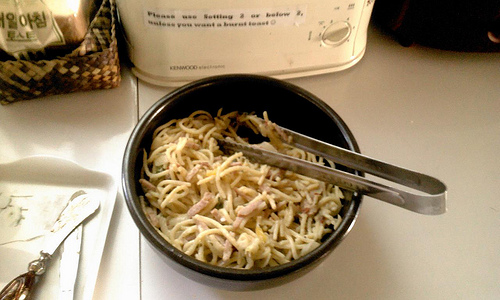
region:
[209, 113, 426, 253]
the tong is silver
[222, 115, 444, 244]
tong in the bowl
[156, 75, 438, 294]
tong in the bowl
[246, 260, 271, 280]
edge of a bowl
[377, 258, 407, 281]
part of a shade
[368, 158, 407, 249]
part of a handle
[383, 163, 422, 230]
part of a handle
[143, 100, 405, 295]
pasta in a bowl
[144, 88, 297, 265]
pasta in a bowl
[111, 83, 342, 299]
the bowl is black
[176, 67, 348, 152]
the bowl is black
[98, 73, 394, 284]
a bowl of pasta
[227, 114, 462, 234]
silver tongs sitting in the pasta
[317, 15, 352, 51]
white dial on the side of the toaster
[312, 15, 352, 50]
numbers around the knob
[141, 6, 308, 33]
sign on the toaster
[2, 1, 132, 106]
woven basket sitting next to the toaster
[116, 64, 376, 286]
black bowl with food in it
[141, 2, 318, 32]
white piece of paper taped onto the toaster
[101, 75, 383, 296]
bowl on the counter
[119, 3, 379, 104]
white toaster on the counter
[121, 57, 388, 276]
a bowl of noodles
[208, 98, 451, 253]
metal tongs in the bowl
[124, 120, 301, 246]
the noodles are white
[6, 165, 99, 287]
silverware on a tray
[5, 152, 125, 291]
the tray is white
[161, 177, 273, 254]
pieces of meat in the noodles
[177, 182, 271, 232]
the mat is pink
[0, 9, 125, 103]
a basket to the upper left of the bowl